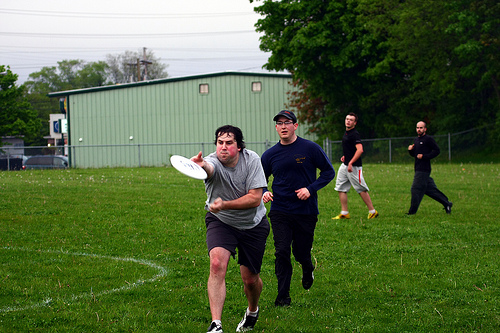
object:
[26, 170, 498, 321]
field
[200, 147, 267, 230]
gray t-shirt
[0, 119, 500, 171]
fence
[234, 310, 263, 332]
shoe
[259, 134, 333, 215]
top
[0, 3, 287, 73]
gray sky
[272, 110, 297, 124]
cap.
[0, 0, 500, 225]
background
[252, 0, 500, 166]
trees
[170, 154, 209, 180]
disc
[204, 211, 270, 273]
pants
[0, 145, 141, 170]
fence field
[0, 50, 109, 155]
trees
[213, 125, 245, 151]
hair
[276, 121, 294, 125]
glasses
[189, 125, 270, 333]
guy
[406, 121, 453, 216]
guys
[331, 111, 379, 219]
man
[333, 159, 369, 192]
shorts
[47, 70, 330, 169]
building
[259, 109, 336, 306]
man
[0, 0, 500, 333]
photo